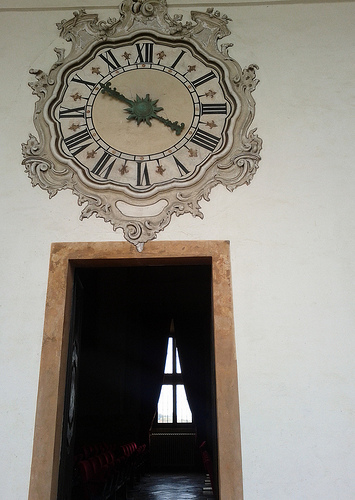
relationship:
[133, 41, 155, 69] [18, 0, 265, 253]
number on clock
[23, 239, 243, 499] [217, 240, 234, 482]
door made of marble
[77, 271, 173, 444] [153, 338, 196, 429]
drapes on window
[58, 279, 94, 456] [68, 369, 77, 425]
screen showing woman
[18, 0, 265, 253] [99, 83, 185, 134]
clock with hands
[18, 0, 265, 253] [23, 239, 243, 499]
clock over door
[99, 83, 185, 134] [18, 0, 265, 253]
hands are on clock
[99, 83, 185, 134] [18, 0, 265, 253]
hands on clock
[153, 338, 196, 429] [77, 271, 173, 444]
window has drapes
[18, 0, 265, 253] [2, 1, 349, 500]
clock on walls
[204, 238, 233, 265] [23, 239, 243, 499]
corner of door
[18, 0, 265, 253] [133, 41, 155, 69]
clock with number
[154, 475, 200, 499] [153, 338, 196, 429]
reflection of light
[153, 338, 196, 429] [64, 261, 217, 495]
window in room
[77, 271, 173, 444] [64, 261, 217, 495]
drapes in room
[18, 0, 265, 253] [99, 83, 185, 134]
clock has hands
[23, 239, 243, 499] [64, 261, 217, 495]
door to room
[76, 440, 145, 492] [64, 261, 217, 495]
seats in room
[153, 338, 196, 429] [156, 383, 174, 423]
window has panes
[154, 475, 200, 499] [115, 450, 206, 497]
reflection on floor